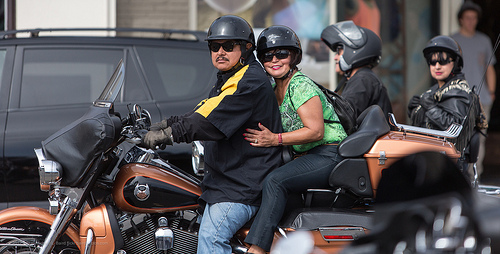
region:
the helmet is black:
[211, 23, 240, 38]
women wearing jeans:
[258, 182, 280, 214]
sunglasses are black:
[265, 47, 292, 64]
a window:
[33, 50, 112, 102]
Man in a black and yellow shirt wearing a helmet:
[186, 12, 271, 205]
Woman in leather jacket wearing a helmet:
[406, 31, 486, 162]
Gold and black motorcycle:
[6, 108, 468, 251]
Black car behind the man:
[5, 23, 249, 202]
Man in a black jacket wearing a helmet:
[317, 18, 396, 137]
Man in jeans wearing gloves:
[142, 15, 278, 251]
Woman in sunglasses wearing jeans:
[247, 24, 352, 252]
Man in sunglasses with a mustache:
[200, 15, 256, 118]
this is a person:
[153, 10, 263, 250]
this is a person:
[248, 3, 355, 252]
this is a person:
[399, 32, 499, 194]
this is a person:
[445, 3, 497, 199]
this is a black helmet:
[202, 8, 259, 73]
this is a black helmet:
[316, 15, 384, 73]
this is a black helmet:
[409, 23, 476, 83]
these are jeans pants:
[189, 188, 247, 250]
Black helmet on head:
[203, 9, 246, 74]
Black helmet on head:
[314, 11, 370, 76]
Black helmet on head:
[412, 27, 474, 89]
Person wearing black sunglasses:
[200, 14, 249, 76]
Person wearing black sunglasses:
[260, 24, 292, 86]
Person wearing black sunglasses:
[425, 24, 456, 91]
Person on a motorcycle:
[186, 6, 256, 246]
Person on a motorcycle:
[237, 11, 307, 230]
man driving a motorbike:
[140, 16, 282, 252]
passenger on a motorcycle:
[246, 20, 346, 252]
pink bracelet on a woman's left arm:
[276, 131, 283, 144]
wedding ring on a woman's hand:
[253, 137, 258, 144]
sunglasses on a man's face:
[206, 40, 240, 57]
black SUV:
[0, 20, 278, 220]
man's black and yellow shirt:
[164, 55, 285, 207]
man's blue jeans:
[196, 186, 258, 251]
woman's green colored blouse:
[271, 70, 351, 152]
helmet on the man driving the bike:
[202, 15, 251, 45]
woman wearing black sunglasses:
[262, 48, 294, 59]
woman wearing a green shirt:
[277, 71, 347, 150]